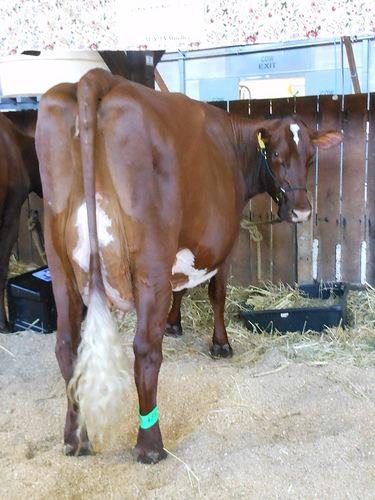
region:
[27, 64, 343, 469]
Dairy cow eating some hay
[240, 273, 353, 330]
Hay in a container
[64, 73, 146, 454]
Tail of a cow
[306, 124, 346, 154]
Ear of a cow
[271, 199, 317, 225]
Nose of a cow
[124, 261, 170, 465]
Back leg of a cow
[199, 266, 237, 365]
Front leg of a cow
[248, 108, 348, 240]
Cow looking at something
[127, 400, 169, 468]
Tag on the leg of a cow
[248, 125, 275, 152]
Tag on the ear of a cow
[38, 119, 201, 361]
the cow has tail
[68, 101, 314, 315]
the cow has tail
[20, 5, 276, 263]
the cow has tail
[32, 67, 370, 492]
Cow standing in hay.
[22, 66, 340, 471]
Cow is brown and white.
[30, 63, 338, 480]
Tag on rear right leg.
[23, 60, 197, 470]
The tag is green.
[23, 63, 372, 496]
Cow looking into camera.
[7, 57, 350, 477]
Cow is milking cow.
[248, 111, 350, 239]
Cow has two ears.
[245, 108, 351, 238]
Cow has two eyes.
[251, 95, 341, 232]
Cows eyes are opened.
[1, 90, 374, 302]
Fence facing the cow.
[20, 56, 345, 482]
light brown cow standing in pen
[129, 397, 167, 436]
light green identification band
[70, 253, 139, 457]
white tassel on cow tail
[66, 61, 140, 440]
tail of brown cow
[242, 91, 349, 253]
brown cow with white marking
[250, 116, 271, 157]
yellow livestock identification tag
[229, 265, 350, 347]
plastic wooden feed bin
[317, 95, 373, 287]
wooden fence panels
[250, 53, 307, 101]
white door with exit sign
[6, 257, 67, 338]
plastic white water container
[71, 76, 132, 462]
the tail of a cow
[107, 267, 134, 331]
an utter of a cow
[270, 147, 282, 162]
an eye of a cow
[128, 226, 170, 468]
the hind leg of a cow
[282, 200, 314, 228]
the nose of a cow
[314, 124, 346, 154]
an eye of a cow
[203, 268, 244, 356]
the front leg of a cow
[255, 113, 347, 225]
the head of a cow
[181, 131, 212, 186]
the fur of a cow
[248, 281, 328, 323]
hay in a feeder